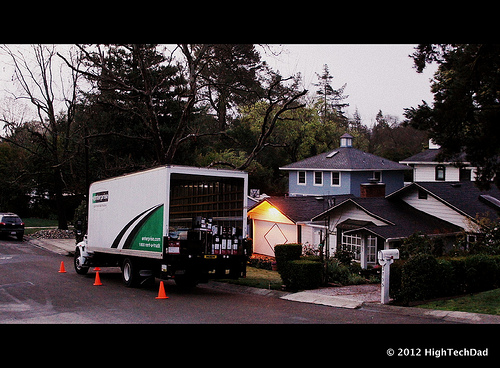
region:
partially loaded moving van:
[72, 162, 248, 294]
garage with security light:
[247, 191, 354, 258]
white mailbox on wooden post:
[374, 248, 399, 303]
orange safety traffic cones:
[54, 257, 169, 299]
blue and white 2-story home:
[279, 129, 414, 196]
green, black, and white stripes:
[110, 203, 161, 249]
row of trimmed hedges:
[390, 252, 499, 302]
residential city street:
[2, 241, 469, 326]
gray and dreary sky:
[1, 45, 453, 125]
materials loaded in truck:
[167, 213, 242, 254]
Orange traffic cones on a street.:
[45, 258, 170, 298]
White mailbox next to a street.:
[371, 246, 401, 306]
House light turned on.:
[246, 195, 291, 230]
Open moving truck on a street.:
[65, 150, 250, 280]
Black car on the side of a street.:
[0, 212, 30, 237]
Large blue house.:
[250, 115, 495, 265]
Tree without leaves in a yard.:
[3, 42, 124, 227]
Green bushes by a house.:
[267, 241, 330, 293]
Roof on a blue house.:
[276, 124, 416, 194]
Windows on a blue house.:
[288, 168, 362, 199]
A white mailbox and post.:
[365, 238, 412, 313]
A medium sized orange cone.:
[147, 273, 177, 307]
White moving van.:
[60, 149, 267, 298]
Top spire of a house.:
[328, 118, 373, 158]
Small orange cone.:
[85, 262, 110, 293]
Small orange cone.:
[52, 249, 72, 280]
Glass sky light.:
[320, 145, 344, 162]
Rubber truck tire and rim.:
[113, 248, 149, 290]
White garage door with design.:
[245, 215, 306, 266]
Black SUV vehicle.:
[0, 204, 34, 256]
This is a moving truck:
[66, 156, 250, 272]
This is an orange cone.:
[148, 270, 177, 302]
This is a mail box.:
[366, 244, 402, 299]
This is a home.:
[248, 187, 497, 304]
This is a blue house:
[269, 124, 410, 204]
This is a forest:
[3, 36, 497, 232]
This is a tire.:
[112, 254, 145, 291]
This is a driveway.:
[279, 281, 368, 313]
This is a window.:
[328, 171, 342, 188]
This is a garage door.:
[249, 216, 297, 262]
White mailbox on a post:
[373, 245, 402, 307]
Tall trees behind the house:
[75, 50, 499, 170]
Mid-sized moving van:
[69, 162, 255, 282]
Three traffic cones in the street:
[52, 257, 170, 302]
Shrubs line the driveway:
[269, 242, 499, 310]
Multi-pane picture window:
[333, 217, 380, 267]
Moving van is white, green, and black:
[63, 167, 168, 274]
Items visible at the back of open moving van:
[165, 167, 257, 269]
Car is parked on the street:
[3, 207, 36, 250]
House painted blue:
[278, 126, 410, 196]